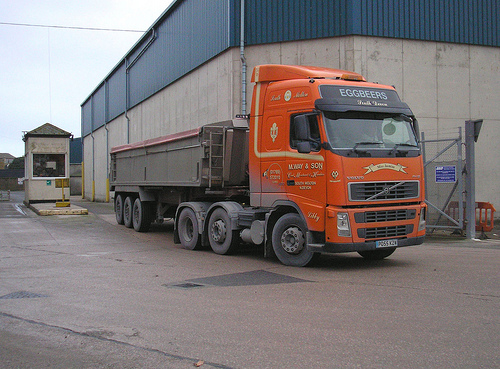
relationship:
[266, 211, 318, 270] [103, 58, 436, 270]
wheel of truck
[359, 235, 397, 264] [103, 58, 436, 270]
wheel of truck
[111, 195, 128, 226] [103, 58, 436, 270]
tire of truck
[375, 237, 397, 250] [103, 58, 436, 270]
license plate on truck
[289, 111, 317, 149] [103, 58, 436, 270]
mirror of truck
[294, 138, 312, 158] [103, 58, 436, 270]
mirror of truck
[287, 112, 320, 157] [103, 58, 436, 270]
window of truck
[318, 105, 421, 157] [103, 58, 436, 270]
windshield of truck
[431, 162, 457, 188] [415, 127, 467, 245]
sign on fence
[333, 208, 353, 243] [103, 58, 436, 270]
headlight of truck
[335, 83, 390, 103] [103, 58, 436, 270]
word on truck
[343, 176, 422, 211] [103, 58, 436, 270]
grill on truck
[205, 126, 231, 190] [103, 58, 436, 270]
ladder on truck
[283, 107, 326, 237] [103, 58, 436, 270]
door of truck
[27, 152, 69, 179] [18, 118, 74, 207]
window on booth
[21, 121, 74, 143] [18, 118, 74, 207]
roof of booth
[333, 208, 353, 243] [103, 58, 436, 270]
headlight on truck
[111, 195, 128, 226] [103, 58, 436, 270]
tire on truck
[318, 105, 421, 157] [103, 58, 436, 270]
windshield on truck